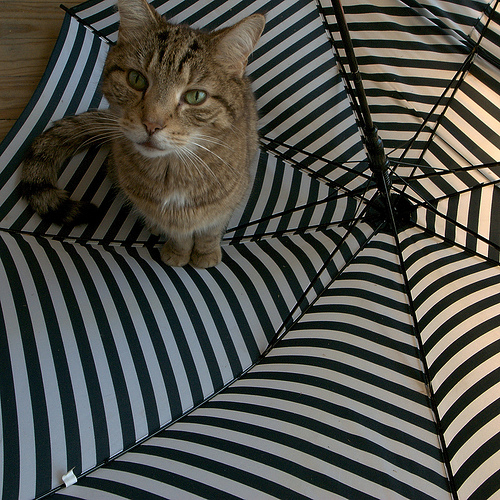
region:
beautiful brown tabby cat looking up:
[19, 0, 291, 282]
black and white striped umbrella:
[8, 5, 498, 488]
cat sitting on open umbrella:
[18, 0, 265, 282]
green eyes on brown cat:
[119, 61, 210, 113]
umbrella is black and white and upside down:
[6, 16, 496, 485]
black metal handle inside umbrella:
[322, 3, 434, 250]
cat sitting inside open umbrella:
[17, 6, 484, 484]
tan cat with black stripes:
[20, 4, 265, 271]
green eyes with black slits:
[123, 63, 208, 107]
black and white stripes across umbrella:
[6, 5, 491, 493]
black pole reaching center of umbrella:
[330, 9, 417, 234]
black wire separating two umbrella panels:
[30, 215, 380, 494]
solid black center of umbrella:
[362, 189, 419, 238]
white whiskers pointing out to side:
[51, 112, 234, 188]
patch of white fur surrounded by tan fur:
[150, 181, 205, 225]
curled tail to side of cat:
[17, 12, 144, 234]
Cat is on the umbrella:
[0, 0, 499, 499]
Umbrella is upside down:
[1, 1, 496, 498]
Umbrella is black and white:
[0, 0, 497, 496]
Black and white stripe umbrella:
[1, 2, 498, 498]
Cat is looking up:
[20, 0, 267, 269]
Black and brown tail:
[18, 108, 103, 227]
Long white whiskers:
[52, 104, 240, 196]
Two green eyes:
[119, 63, 210, 108]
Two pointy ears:
[112, 0, 266, 75]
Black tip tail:
[81, 202, 103, 226]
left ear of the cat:
[211, 8, 270, 80]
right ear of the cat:
[110, 0, 165, 50]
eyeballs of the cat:
[122, 65, 211, 112]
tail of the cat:
[20, 85, 109, 250]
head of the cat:
[105, 2, 265, 159]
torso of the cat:
[122, 150, 249, 223]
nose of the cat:
[144, 119, 169, 136]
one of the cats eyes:
[180, 80, 206, 115]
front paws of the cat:
[160, 242, 220, 267]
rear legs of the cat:
[159, 224, 229, 271]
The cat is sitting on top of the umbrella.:
[92, 33, 264, 303]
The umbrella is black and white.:
[15, 270, 497, 460]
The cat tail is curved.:
[22, 129, 95, 246]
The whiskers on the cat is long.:
[172, 143, 233, 193]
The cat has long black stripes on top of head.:
[141, 25, 213, 92]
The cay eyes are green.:
[110, 65, 223, 115]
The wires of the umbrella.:
[279, 136, 431, 266]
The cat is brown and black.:
[88, 23, 237, 270]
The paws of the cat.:
[154, 228, 221, 271]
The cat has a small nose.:
[138, 121, 161, 138]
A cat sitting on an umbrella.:
[19, 0, 268, 270]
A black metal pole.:
[326, 0, 421, 230]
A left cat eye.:
[179, 82, 210, 112]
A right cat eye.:
[123, 65, 153, 97]